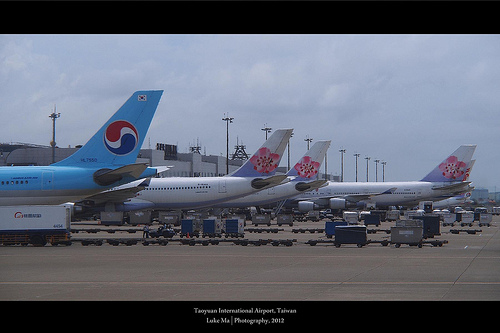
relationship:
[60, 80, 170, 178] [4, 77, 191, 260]
tail of aircraft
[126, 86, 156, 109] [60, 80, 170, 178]
flag on top of tail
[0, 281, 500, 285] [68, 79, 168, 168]
line on tail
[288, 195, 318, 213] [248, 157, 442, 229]
engine on aircraft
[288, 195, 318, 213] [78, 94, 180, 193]
engine under wings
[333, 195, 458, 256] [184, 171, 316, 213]
luggage boxes behind aircraft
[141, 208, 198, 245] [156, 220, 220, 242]
mechanic crew near luggage vehicle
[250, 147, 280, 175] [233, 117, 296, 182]
flower on tail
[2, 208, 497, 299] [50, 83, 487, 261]
ground on airport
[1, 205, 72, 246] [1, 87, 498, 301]
service vehicle on airport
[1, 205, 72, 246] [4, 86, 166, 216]
service vehicle next to aircraft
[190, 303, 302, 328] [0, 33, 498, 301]
text describing photo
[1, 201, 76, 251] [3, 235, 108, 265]
service vehicle on gray tarmack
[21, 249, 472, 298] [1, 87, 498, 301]
pavement at airport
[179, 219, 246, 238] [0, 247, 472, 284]
carts on tarmac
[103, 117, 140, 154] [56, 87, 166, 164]
logo on tail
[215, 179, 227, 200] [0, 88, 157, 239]
door on airplane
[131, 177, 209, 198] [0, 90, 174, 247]
windows along aircraft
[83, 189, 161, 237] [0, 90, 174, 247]
engine on aircraft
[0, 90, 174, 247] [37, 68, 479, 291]
aircraft at terminal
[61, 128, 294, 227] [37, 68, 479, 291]
aircraft at terminal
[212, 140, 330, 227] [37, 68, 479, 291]
aircraft at terminal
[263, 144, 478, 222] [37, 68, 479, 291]
aircraft at terminal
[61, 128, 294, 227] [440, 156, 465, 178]
aircraft with flower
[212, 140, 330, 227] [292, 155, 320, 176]
aircraft with flower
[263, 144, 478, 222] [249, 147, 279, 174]
aircraft with flower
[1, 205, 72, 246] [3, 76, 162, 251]
service vehicle near plane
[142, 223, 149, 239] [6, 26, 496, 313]
mechanic crew at airport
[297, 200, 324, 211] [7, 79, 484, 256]
engine on plane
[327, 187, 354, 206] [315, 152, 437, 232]
engines on plane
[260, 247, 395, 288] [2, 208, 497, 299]
concrete of ground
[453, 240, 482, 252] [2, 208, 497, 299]
white lines on ground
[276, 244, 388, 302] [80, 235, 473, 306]
line on ground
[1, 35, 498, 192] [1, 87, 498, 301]
skies over airport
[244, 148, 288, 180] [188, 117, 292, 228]
flower on planes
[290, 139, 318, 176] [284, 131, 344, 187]
flower on planes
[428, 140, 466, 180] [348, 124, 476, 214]
flower on planes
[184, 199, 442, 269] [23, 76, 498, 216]
carts next to planes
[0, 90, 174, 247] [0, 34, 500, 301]
aircraft at airport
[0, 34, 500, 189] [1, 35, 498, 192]
clouds in skies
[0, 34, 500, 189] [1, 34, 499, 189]
clouds in sky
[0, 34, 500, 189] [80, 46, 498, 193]
clouds in sky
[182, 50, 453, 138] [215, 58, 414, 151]
clouds in sky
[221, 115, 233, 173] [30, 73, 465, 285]
light at airport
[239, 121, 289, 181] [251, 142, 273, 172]
tail with flower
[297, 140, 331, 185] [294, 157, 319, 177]
tail with flower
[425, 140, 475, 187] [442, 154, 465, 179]
tail with flower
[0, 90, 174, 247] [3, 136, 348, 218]
aircraft parked at terminal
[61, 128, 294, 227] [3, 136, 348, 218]
aircraft parked at terminal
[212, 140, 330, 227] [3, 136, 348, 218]
aircraft parked at terminal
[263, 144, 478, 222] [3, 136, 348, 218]
aircraft parked at terminal